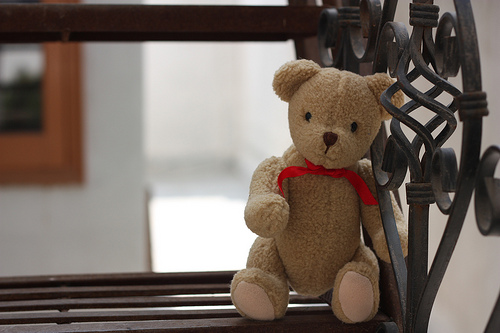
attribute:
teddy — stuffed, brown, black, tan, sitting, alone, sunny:
[265, 62, 400, 312]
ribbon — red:
[278, 159, 380, 217]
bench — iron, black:
[5, 271, 377, 332]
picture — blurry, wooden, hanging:
[3, 43, 86, 187]